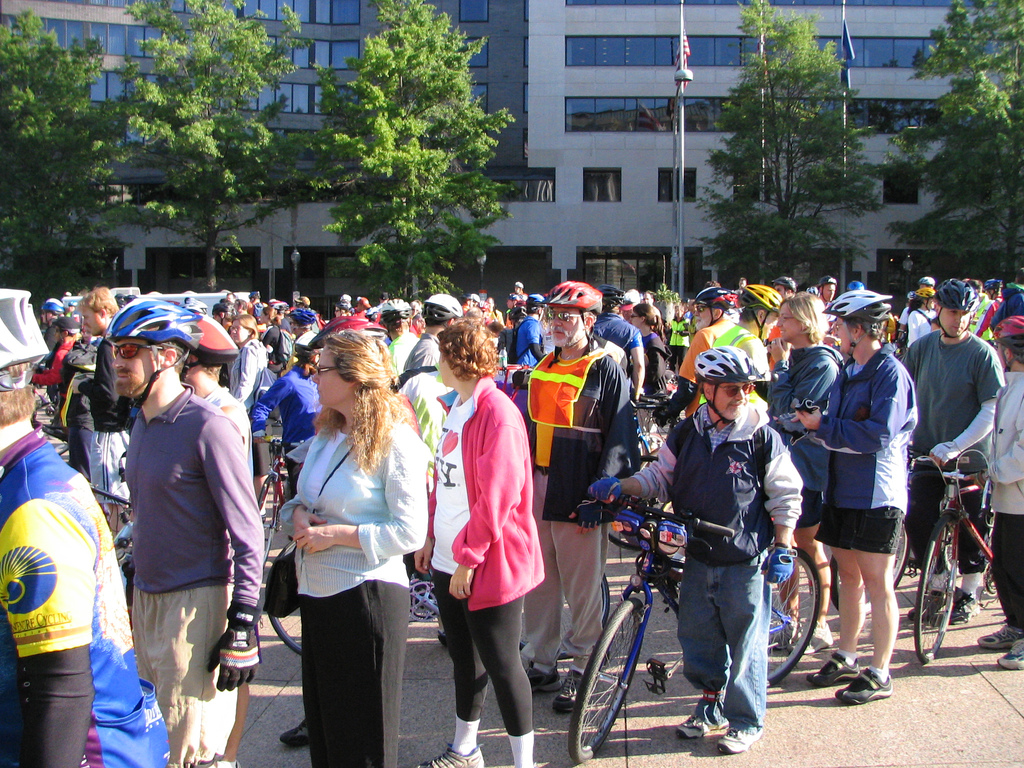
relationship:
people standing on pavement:
[139, 299, 1019, 522] [492, 571, 1018, 742]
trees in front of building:
[82, 55, 497, 233] [82, 55, 967, 233]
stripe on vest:
[529, 363, 588, 389] [523, 345, 609, 469]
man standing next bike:
[883, 266, 1007, 639] [585, 504, 698, 716]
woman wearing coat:
[408, 305, 555, 765] [475, 418, 542, 576]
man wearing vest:
[511, 266, 635, 739] [520, 355, 609, 461]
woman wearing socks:
[408, 305, 555, 765] [441, 712, 544, 766]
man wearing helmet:
[591, 328, 812, 765] [94, 296, 215, 354]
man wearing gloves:
[899, 271, 1005, 645] [751, 547, 803, 591]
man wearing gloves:
[110, 309, 245, 763] [582, 470, 804, 594]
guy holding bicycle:
[580, 333, 821, 766] [566, 526, 834, 708]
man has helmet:
[483, 277, 712, 490] [483, 277, 712, 490]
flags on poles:
[662, 17, 860, 100] [635, 33, 709, 215]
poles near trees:
[635, 33, 709, 215] [21, 3, 471, 278]